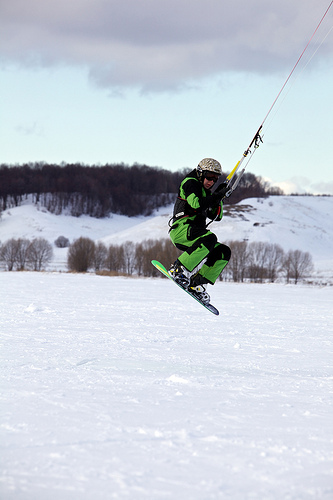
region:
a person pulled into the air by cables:
[145, 59, 275, 314]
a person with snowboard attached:
[158, 145, 246, 323]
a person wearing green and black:
[169, 143, 236, 289]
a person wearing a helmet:
[197, 157, 221, 176]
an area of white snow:
[59, 318, 268, 451]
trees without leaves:
[28, 160, 125, 204]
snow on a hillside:
[279, 196, 328, 250]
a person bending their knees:
[165, 220, 235, 304]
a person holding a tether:
[209, 181, 242, 218]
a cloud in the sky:
[47, 22, 258, 104]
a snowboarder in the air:
[47, 120, 291, 331]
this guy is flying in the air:
[131, 148, 265, 322]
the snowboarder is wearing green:
[142, 141, 251, 320]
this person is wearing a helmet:
[192, 151, 222, 191]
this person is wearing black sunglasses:
[202, 169, 229, 185]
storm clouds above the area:
[9, 8, 322, 79]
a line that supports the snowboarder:
[230, 21, 322, 157]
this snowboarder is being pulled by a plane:
[139, 138, 282, 310]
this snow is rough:
[26, 301, 310, 477]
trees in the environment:
[6, 239, 307, 278]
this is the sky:
[127, 16, 224, 126]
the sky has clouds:
[124, 24, 174, 60]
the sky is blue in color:
[206, 94, 237, 107]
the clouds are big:
[129, 32, 183, 65]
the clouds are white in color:
[197, 25, 247, 61]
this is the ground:
[111, 426, 179, 470]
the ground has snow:
[148, 456, 205, 499]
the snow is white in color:
[161, 445, 188, 476]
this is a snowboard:
[148, 255, 166, 276]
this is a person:
[172, 140, 227, 294]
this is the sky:
[112, 35, 200, 119]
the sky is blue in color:
[77, 92, 136, 122]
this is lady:
[171, 156, 222, 309]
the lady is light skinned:
[199, 180, 212, 187]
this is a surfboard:
[151, 262, 188, 301]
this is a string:
[288, 33, 299, 130]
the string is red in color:
[263, 79, 283, 108]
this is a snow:
[204, 348, 331, 431]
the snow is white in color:
[184, 372, 284, 435]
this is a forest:
[117, 172, 146, 202]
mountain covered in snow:
[75, 195, 331, 266]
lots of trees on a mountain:
[0, 160, 284, 217]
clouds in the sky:
[0, 0, 332, 97]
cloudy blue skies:
[0, 0, 332, 194]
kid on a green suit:
[170, 157, 230, 304]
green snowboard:
[151, 258, 218, 314]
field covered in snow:
[0, 270, 332, 498]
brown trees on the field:
[0, 238, 332, 284]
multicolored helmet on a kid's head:
[196, 157, 221, 174]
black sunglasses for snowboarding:
[204, 170, 218, 181]